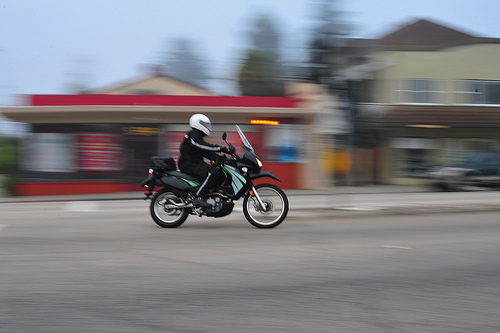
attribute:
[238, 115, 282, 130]
lights — blurry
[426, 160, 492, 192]
blurryvehicle — blurry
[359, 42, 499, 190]
yellow house — blurry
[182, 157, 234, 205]
pants — man's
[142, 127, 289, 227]
motorcycle — black, green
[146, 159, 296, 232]
bike — black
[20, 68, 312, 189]
business — red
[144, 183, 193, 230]
tire — back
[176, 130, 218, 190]
jacket — man's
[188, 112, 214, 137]
helmet — white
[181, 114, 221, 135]
helmet — white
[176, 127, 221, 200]
clothing — black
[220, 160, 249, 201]
trim — green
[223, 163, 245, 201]
designs — blue, green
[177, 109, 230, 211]
rider — bike